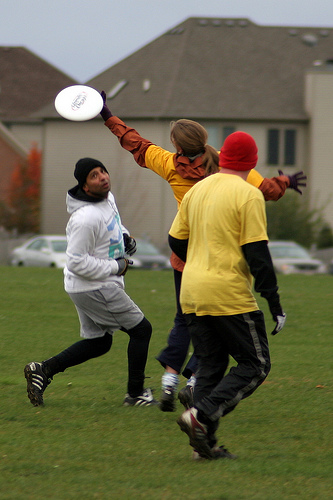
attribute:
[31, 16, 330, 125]
roof — brown